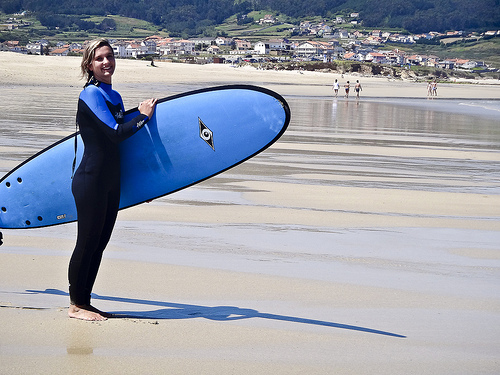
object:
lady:
[67, 32, 157, 322]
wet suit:
[67, 83, 146, 307]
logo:
[197, 116, 214, 152]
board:
[0, 84, 292, 229]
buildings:
[456, 59, 483, 68]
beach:
[0, 46, 500, 374]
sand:
[329, 193, 456, 247]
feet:
[68, 304, 107, 321]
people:
[354, 80, 363, 100]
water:
[290, 97, 499, 178]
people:
[426, 81, 434, 96]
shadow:
[24, 288, 409, 339]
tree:
[36, 11, 95, 31]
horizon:
[1, 1, 500, 47]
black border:
[226, 84, 271, 92]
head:
[80, 38, 116, 77]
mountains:
[0, 0, 500, 34]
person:
[151, 59, 159, 67]